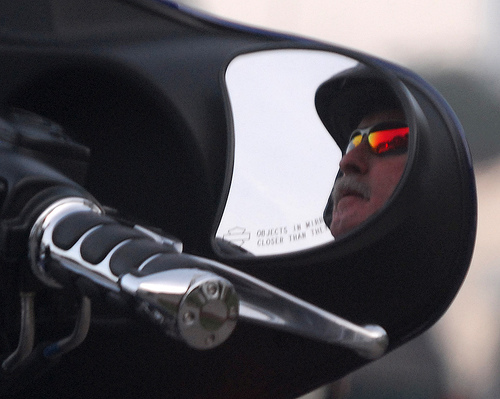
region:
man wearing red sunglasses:
[325, 113, 399, 156]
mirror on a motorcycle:
[211, 30, 464, 260]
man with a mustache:
[327, 172, 381, 204]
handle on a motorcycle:
[46, 186, 217, 348]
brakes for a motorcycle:
[146, 219, 367, 352]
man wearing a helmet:
[298, 60, 399, 129]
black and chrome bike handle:
[58, 197, 227, 334]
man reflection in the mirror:
[218, 43, 426, 270]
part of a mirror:
[439, 248, 452, 258]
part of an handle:
[305, 302, 309, 308]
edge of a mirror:
[341, 193, 346, 212]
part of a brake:
[138, 267, 150, 322]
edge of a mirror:
[353, 270, 356, 273]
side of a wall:
[430, 338, 433, 345]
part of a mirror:
[256, 169, 266, 224]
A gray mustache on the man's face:
[327, 174, 370, 202]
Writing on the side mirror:
[221, 216, 333, 252]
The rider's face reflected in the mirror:
[310, 70, 409, 246]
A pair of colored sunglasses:
[342, 128, 410, 154]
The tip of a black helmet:
[311, 63, 400, 137]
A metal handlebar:
[36, 191, 387, 365]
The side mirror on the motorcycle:
[176, 22, 467, 365]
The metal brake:
[214, 258, 388, 357]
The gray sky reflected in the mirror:
[217, 50, 354, 259]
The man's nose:
[340, 144, 374, 174]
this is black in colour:
[5, 6, 105, 90]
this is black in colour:
[99, 77, 178, 177]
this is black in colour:
[126, 359, 227, 392]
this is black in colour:
[257, 338, 299, 378]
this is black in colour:
[418, 139, 461, 226]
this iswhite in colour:
[244, 172, 301, 228]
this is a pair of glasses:
[341, 117, 408, 156]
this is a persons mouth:
[326, 175, 371, 205]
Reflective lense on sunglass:
[368, 123, 418, 157]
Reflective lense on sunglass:
[337, 126, 368, 158]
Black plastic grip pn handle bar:
[110, 236, 168, 273]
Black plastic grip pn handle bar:
[147, 252, 204, 277]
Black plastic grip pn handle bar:
[81, 226, 113, 254]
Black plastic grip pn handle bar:
[56, 208, 77, 250]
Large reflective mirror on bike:
[210, 15, 418, 277]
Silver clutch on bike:
[40, 203, 335, 383]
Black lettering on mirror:
[240, 219, 361, 257]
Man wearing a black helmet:
[295, 64, 420, 235]